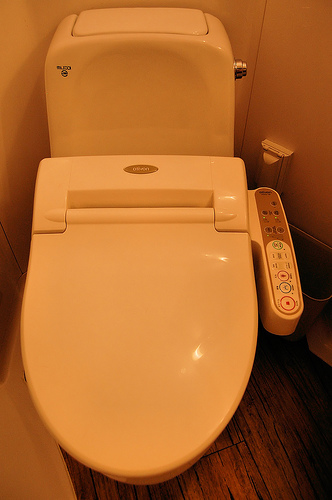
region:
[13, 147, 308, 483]
closed toilet seat of toilet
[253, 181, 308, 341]
automatic control buttons of toilet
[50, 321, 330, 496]
wooden floor of bathroom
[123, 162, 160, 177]
brand logo of toilet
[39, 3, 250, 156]
white tank with silver flush button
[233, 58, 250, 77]
silver flush button on side of toilet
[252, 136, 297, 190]
white outlet in wall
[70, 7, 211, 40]
opening to tank of toilet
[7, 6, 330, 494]
white painted walls of toilet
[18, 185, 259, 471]
closed oval white hinged toilet seat lid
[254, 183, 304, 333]
a white control panel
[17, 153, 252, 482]
he seat of a toilet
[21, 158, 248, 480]
a white toilet lid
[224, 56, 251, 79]
electronic toilet flushing mechanism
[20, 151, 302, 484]
a computerized electric toilet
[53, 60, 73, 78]
a black and white company logo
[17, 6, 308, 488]
clean public bathroom toilet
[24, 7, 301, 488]
a toilet with a controller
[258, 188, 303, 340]
buttons to control a toilet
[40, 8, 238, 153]
a white porcelain toilet tank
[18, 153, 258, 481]
a white plastic toilet seat lid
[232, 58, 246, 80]
a chrome flush valve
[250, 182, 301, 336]
an electronic toilet control panel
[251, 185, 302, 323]
electric panel next to toilet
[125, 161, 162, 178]
emblem on the toilet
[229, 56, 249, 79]
chrome button on the toilet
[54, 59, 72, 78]
green logo on the toilet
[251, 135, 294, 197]
gray box on the wall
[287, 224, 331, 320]
waste basket next to the toilet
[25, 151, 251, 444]
white toilet in the bathroom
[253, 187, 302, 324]
panel next to the toilet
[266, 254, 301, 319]
buttons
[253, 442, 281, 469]
a wooden floor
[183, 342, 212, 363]
light on the lid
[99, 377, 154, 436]
the toilet lid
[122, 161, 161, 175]
logo on the toilet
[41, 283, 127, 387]
the lit is white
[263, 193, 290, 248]
small buttons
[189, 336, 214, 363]
a reflection of light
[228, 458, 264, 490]
the floor is brown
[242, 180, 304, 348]
the control panel of a toilet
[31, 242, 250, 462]
the lid of a toilet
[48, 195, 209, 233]
the hinge of a toilet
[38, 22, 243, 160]
the tank of a toilet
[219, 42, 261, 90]
the flusher of a toilet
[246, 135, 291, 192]
the outlet on a wall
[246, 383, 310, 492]
a floor that is hardwood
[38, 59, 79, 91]
the logo of a toilet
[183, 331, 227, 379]
a reflection on a toilet lid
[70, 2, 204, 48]
the toilet tank lid of a toilet